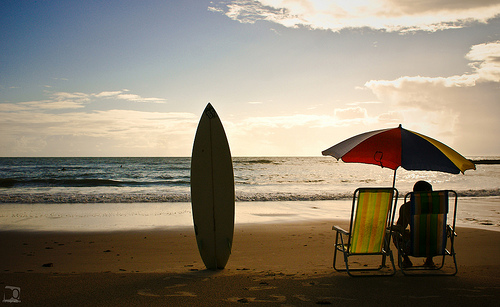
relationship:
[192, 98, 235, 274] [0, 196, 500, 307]
surfboard on beach grounds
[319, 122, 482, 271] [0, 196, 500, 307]
umbrella on beach grounds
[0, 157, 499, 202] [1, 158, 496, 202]
ocean waves in ocean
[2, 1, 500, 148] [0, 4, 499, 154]
clouds against sky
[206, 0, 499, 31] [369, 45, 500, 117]
clouds has edge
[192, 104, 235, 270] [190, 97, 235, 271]
surfboard has edge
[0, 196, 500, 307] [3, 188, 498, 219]
beach grounds has edge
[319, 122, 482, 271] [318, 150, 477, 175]
umbrella has edge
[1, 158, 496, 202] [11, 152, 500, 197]
ocean filled with water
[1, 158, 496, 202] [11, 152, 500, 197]
ocean with water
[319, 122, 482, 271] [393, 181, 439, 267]
umbrella over man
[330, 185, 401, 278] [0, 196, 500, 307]
chair sitting on beach grounds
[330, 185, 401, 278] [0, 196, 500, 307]
chair on beach grounds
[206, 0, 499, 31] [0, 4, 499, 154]
clouds in sky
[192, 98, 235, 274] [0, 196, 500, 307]
surfboard stuck in beach grounds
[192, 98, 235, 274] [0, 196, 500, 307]
surfboard standing in beach grounds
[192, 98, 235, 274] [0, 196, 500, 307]
surfboard in beach grounds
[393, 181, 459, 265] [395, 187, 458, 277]
man on chair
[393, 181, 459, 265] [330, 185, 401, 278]
man sitting on chair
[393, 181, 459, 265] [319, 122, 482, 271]
man under umbrella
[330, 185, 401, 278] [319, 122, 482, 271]
chair under umbrella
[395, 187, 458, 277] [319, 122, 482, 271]
chair under umbrella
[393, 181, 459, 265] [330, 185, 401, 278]
man on chair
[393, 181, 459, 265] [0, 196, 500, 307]
man at beach grounds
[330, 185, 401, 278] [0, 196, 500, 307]
chair at beach grounds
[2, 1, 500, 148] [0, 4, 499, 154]
clouds in sky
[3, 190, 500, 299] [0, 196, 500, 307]
beach grounds made of beach grounds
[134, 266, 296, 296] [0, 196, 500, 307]
print in beach grounds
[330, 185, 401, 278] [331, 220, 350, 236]
chair has arm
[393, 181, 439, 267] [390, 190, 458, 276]
man sitting in chair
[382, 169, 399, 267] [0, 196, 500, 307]
pole stuck in beach grounds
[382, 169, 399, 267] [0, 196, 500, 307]
pole in beach grounds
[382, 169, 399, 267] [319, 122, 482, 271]
pole to umbrella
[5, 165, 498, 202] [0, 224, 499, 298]
ocean waves lapping shore